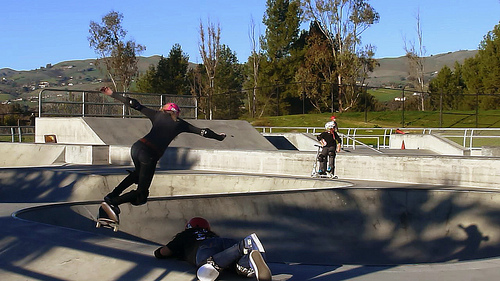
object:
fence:
[207, 82, 500, 128]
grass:
[252, 89, 499, 148]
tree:
[399, 5, 428, 112]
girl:
[99, 85, 226, 223]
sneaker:
[103, 195, 120, 215]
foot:
[102, 196, 124, 215]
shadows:
[176, 169, 499, 280]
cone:
[399, 138, 405, 149]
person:
[154, 216, 274, 281]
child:
[313, 120, 345, 174]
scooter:
[308, 144, 341, 180]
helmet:
[160, 102, 182, 113]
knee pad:
[126, 188, 151, 208]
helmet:
[183, 217, 213, 229]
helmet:
[322, 120, 338, 133]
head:
[323, 121, 340, 134]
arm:
[111, 90, 158, 119]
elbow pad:
[123, 97, 138, 108]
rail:
[36, 88, 213, 121]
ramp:
[76, 116, 278, 150]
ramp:
[341, 148, 439, 155]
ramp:
[10, 186, 498, 267]